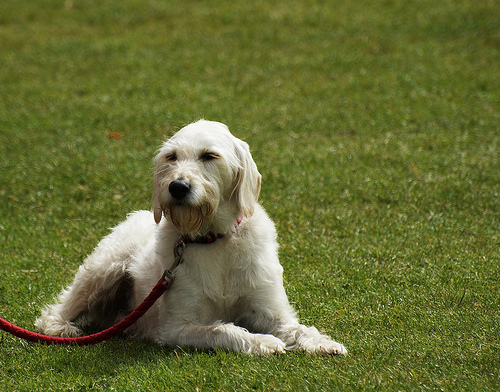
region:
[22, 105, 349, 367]
dog is color white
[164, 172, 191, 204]
nose of dog is black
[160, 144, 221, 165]
eyes of dog are black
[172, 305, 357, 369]
front legs of dog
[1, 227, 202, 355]
leash is color red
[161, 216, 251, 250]
collar of dog is red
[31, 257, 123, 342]
back legs of dog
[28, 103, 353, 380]
dog lying on green grass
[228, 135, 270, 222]
right ear of dog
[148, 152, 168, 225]
left ear of dog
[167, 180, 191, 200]
black nose on the dog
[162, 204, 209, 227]
mouth hair is dirty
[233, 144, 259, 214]
the ear is down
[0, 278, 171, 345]
red dog leash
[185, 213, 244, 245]
red dog collar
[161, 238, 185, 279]
the leash buckle is silver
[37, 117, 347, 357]
the dog is laying down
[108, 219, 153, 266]
white dog fur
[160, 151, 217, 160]
black eyes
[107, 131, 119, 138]
brown leaf on the grass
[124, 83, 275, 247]
head of a dog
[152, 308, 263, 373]
leg of a dog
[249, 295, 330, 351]
leg of a dog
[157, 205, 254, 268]
collar of a dog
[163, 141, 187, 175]
eye of a dog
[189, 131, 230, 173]
eye of a dog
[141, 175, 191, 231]
ear of a dog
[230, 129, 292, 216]
ear of a dog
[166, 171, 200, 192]
nose of a dog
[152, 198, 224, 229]
mouth of a dog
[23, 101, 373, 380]
a dog is lying down on a field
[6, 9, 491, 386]
the field has green grass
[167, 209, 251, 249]
the dog has a red collar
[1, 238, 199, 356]
a red leash is attached to the collar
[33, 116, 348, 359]
the dog is mostly white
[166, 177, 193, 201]
the dog's nose is black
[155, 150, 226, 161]
the dog's eyes are black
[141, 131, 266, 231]
long floppy ears are on the dog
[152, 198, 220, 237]
the dog has a stained beard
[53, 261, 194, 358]
the dog is black underneath his leg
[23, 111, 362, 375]
dog laying on the grass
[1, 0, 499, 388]
green grass on the ground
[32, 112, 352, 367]
long white hair on the body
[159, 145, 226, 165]
a pair of dark eyes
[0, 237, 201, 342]
red leash attached to the collar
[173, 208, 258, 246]
collar around the neck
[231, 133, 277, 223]
floppy ear laying down the face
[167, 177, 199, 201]
black nose on the tip of the snout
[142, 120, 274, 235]
head is turned to the side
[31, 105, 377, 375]
long haired dog